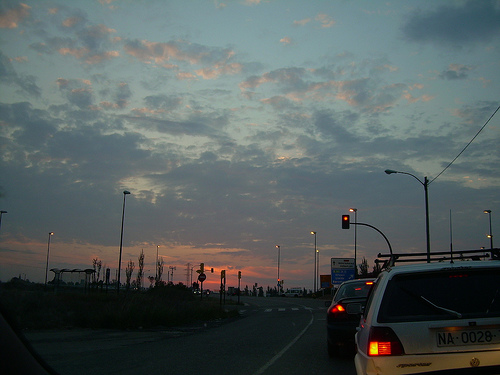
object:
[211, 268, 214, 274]
stoplight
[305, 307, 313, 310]
white lines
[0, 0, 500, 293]
cloud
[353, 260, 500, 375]
car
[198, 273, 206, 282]
sign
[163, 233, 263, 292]
sunset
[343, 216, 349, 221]
light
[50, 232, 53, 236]
street light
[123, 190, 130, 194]
streetlight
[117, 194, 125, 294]
tall streetlight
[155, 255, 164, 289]
trees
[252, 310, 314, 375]
line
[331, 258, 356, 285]
sign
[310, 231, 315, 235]
lights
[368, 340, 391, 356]
brake light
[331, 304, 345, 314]
brake light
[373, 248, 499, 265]
roofrack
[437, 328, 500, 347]
license plate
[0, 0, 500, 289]
sky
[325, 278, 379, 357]
car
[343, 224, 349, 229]
streetlight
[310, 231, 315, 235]
street light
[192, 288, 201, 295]
car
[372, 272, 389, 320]
edge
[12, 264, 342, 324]
distance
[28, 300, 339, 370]
street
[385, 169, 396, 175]
light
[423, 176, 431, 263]
pole